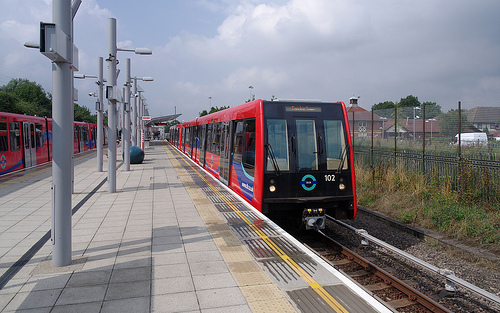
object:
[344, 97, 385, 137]
home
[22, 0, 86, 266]
platform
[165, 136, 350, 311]
strip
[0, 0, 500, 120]
sky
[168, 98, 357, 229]
trai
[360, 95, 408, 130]
ground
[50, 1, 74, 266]
pole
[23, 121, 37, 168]
door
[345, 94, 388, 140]
building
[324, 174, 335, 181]
102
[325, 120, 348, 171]
front window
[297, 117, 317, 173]
front window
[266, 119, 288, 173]
front window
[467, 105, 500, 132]
buildings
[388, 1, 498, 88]
clouds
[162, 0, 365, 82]
cloud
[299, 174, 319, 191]
logo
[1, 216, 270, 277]
shadow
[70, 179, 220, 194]
shadow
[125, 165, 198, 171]
shadow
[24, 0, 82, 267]
utility pole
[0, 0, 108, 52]
cloud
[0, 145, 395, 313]
platform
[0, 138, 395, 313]
train area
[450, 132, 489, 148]
van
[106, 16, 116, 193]
pole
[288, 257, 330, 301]
line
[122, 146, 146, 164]
ball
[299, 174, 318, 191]
circle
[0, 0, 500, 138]
background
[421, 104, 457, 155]
wire fencing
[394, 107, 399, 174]
poles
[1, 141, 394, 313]
train station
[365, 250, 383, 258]
dirt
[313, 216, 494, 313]
track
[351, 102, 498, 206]
fence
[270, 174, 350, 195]
black background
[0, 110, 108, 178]
passenger train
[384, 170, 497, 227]
grass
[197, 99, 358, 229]
first car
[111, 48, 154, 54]
streetlight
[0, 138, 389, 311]
ground